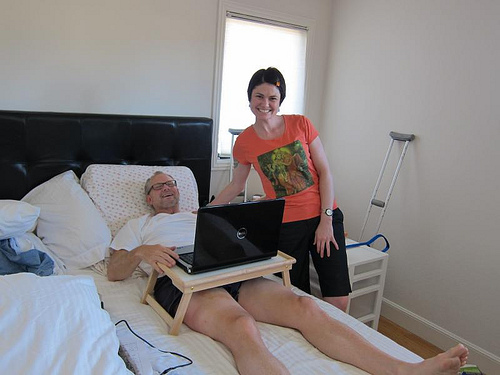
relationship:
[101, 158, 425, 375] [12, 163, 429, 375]
man in bed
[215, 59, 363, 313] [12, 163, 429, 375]
woman standing beside bed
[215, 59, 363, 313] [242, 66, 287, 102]
woman with short hair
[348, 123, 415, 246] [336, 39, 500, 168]
crutch against wall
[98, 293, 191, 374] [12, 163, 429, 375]
cord on bed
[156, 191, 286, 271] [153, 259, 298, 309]
laptop on a tray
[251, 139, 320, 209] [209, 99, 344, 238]
design on shirt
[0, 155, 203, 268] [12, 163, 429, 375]
pillow on bed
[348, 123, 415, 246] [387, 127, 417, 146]
crutch with gray pads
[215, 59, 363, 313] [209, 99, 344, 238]
woman in orange shirt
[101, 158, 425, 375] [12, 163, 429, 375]
man lying in bed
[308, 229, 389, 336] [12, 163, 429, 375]
nightstand next to bed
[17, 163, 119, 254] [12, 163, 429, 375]
pillows on bed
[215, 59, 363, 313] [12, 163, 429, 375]
lady next to bed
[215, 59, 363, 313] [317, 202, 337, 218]
woman wearing a watch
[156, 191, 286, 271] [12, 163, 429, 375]
laptop on bed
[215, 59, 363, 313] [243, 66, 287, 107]
woman has brown hair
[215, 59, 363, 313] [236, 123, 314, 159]
woman has orange shirt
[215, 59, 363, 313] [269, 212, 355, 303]
woman has shorts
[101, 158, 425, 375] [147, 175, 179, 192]
man wearing glasses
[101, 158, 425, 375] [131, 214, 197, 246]
man has a white shirt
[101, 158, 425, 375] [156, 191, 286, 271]
man has laptop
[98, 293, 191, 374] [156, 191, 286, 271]
cord next to laptop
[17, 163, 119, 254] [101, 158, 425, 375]
pillows next to man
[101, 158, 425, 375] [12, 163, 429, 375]
man on bed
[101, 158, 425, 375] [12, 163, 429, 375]
man lying on bed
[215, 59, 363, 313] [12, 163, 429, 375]
woman next to bed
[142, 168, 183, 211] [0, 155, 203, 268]
head on pillow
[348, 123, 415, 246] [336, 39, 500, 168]
crutch on wall